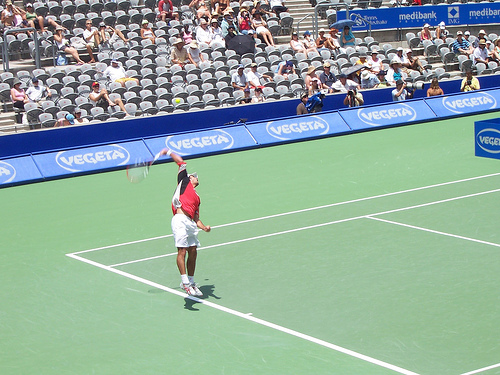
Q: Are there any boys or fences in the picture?
A: No, there are no fences or boys.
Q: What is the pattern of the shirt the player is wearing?
A: The shirt is striped.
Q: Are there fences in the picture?
A: No, there are no fences.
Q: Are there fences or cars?
A: No, there are no fences or cars.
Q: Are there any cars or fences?
A: No, there are no fences or cars.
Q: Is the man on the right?
A: Yes, the man is on the right of the image.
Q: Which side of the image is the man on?
A: The man is on the right of the image.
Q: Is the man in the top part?
A: Yes, the man is in the top of the image.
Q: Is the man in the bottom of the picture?
A: No, the man is in the top of the image.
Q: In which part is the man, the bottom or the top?
A: The man is in the top of the image.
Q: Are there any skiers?
A: No, there are no skiers.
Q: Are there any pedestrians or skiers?
A: No, there are no skiers or pedestrians.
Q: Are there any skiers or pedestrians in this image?
A: No, there are no skiers or pedestrians.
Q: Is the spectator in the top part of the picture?
A: Yes, the spectator is in the top of the image.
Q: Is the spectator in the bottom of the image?
A: No, the spectator is in the top of the image.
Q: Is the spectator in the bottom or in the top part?
A: The spectator is in the top of the image.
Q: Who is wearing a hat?
A: The spectator is wearing a hat.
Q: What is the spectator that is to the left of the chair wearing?
A: The spectator is wearing a hat.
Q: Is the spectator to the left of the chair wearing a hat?
A: Yes, the spectator is wearing a hat.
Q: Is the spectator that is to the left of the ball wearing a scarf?
A: No, the spectator is wearing a hat.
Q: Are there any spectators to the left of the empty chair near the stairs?
A: Yes, there is a spectator to the left of the chair.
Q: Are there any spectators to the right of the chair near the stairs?
A: No, the spectator is to the left of the chair.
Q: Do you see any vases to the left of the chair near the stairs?
A: No, there is a spectator to the left of the chair.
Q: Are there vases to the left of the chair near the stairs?
A: No, there is a spectator to the left of the chair.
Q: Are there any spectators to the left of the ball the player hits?
A: Yes, there is a spectator to the left of the ball.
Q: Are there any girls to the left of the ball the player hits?
A: No, there is a spectator to the left of the ball.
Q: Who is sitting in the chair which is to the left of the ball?
A: The spectator is sitting in the chair.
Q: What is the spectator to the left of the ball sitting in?
A: The spectator is sitting in the chair.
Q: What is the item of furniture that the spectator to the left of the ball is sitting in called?
A: The piece of furniture is a chair.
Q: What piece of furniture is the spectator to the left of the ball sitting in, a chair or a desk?
A: The spectator is sitting in a chair.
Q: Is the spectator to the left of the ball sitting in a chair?
A: Yes, the spectator is sitting in a chair.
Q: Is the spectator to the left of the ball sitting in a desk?
A: No, the spectator is sitting in a chair.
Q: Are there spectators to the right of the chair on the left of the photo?
A: Yes, there is a spectator to the right of the chair.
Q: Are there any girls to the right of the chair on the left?
A: No, there is a spectator to the right of the chair.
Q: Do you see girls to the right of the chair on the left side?
A: No, there is a spectator to the right of the chair.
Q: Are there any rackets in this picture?
A: Yes, there is a racket.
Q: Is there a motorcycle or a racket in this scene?
A: Yes, there is a racket.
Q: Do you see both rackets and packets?
A: No, there is a racket but no packets.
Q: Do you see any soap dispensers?
A: No, there are no soap dispensers.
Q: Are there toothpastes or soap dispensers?
A: No, there are no soap dispensers or toothpastes.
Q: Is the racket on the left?
A: Yes, the racket is on the left of the image.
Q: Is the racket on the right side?
A: No, the racket is on the left of the image.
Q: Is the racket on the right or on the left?
A: The racket is on the left of the image.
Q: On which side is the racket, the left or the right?
A: The racket is on the left of the image.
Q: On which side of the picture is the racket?
A: The racket is on the left of the image.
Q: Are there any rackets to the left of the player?
A: Yes, there is a racket to the left of the player.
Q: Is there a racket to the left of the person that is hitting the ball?
A: Yes, there is a racket to the left of the player.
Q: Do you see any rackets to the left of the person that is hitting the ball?
A: Yes, there is a racket to the left of the player.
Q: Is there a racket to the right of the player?
A: No, the racket is to the left of the player.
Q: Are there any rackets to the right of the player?
A: No, the racket is to the left of the player.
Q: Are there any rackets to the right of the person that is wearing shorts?
A: No, the racket is to the left of the player.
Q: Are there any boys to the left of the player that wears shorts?
A: No, there is a racket to the left of the player.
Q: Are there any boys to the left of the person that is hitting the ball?
A: No, there is a racket to the left of the player.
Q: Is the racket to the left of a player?
A: Yes, the racket is to the left of a player.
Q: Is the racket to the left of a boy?
A: No, the racket is to the left of a player.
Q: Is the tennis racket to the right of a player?
A: No, the tennis racket is to the left of a player.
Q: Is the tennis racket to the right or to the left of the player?
A: The tennis racket is to the left of the player.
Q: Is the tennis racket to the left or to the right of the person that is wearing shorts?
A: The tennis racket is to the left of the player.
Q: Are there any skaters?
A: No, there are no skaters.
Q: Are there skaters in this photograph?
A: No, there are no skaters.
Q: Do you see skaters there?
A: No, there are no skaters.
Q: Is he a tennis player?
A: Yes, that is a tennis player.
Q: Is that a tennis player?
A: Yes, that is a tennis player.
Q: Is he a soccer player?
A: No, that is a tennis player.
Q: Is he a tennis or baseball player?
A: That is a tennis player.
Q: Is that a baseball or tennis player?
A: That is a tennis player.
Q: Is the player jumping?
A: Yes, the player is jumping.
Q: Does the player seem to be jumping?
A: Yes, the player is jumping.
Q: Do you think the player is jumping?
A: Yes, the player is jumping.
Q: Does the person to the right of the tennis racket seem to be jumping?
A: Yes, the player is jumping.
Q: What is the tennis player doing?
A: The player is jumping.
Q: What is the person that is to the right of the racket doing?
A: The player is jumping.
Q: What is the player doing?
A: The player is jumping.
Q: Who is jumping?
A: The player is jumping.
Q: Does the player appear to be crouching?
A: No, the player is jumping.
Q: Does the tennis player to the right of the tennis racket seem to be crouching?
A: No, the player is jumping.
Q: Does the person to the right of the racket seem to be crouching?
A: No, the player is jumping.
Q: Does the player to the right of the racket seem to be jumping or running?
A: The player is jumping.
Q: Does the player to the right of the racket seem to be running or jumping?
A: The player is jumping.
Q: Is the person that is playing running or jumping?
A: The player is jumping.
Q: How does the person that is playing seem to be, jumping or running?
A: The player is jumping.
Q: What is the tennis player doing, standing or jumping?
A: The player is jumping.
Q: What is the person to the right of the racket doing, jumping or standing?
A: The player is jumping.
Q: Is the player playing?
A: Yes, the player is playing.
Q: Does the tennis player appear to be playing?
A: Yes, the player is playing.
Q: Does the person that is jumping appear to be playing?
A: Yes, the player is playing.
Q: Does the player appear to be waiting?
A: No, the player is playing.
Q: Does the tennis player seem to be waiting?
A: No, the player is playing.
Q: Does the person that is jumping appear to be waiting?
A: No, the player is playing.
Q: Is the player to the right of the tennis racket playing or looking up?
A: The player is playing.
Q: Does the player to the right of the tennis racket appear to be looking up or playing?
A: The player is playing.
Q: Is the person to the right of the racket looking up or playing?
A: The player is playing.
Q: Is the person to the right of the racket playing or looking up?
A: The player is playing.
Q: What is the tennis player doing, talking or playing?
A: The player is playing.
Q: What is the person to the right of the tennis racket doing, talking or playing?
A: The player is playing.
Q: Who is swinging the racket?
A: The player is swinging the racket.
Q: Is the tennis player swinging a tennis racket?
A: Yes, the player is swinging a tennis racket.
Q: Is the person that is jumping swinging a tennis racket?
A: Yes, the player is swinging a tennis racket.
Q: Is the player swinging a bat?
A: No, the player is swinging a tennis racket.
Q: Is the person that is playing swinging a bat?
A: No, the player is swinging a tennis racket.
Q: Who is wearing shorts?
A: The player is wearing shorts.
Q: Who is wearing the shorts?
A: The player is wearing shorts.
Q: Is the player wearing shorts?
A: Yes, the player is wearing shorts.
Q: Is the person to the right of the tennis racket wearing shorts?
A: Yes, the player is wearing shorts.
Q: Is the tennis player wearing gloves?
A: No, the player is wearing shorts.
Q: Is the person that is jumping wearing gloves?
A: No, the player is wearing shorts.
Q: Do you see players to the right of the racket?
A: Yes, there is a player to the right of the racket.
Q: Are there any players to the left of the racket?
A: No, the player is to the right of the racket.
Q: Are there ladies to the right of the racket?
A: No, there is a player to the right of the racket.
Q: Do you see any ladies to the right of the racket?
A: No, there is a player to the right of the racket.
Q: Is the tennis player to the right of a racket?
A: Yes, the player is to the right of a racket.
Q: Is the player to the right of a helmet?
A: No, the player is to the right of a racket.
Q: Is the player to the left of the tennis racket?
A: No, the player is to the right of the tennis racket.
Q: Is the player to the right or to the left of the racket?
A: The player is to the right of the racket.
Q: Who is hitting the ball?
A: The player is hitting the ball.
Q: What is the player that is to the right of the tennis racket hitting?
A: The player is hitting the ball.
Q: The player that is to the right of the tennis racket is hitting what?
A: The player is hitting the ball.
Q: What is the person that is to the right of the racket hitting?
A: The player is hitting the ball.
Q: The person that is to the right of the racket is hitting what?
A: The player is hitting the ball.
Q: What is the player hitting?
A: The player is hitting the ball.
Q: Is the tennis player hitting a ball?
A: Yes, the player is hitting a ball.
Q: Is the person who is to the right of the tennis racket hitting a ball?
A: Yes, the player is hitting a ball.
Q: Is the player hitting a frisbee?
A: No, the player is hitting a ball.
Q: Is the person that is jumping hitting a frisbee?
A: No, the player is hitting a ball.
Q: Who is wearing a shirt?
A: The player is wearing a shirt.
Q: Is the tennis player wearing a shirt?
A: Yes, the player is wearing a shirt.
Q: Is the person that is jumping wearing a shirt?
A: Yes, the player is wearing a shirt.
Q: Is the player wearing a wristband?
A: No, the player is wearing a shirt.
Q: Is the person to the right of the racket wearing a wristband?
A: No, the player is wearing a shirt.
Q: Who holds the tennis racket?
A: The player holds the tennis racket.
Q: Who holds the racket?
A: The player holds the tennis racket.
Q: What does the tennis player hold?
A: The player holds the racket.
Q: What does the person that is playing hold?
A: The player holds the racket.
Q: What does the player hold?
A: The player holds the racket.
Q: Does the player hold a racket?
A: Yes, the player holds a racket.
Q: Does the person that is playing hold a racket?
A: Yes, the player holds a racket.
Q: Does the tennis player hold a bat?
A: No, the player holds a racket.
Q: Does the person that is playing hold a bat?
A: No, the player holds a racket.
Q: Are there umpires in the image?
A: No, there are no umpires.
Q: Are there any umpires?
A: No, there are no umpires.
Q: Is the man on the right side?
A: Yes, the man is on the right of the image.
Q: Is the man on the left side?
A: No, the man is on the right of the image.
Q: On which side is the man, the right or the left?
A: The man is on the right of the image.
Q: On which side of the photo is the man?
A: The man is on the right of the image.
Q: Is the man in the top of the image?
A: Yes, the man is in the top of the image.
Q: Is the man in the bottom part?
A: No, the man is in the top of the image.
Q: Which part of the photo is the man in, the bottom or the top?
A: The man is in the top of the image.